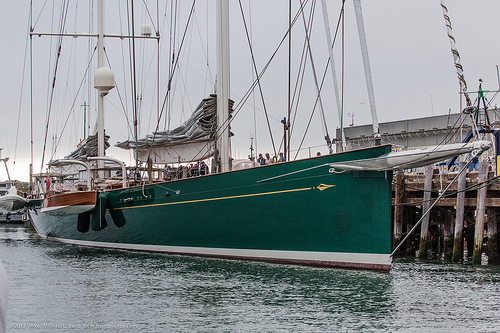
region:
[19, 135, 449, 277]
a green sail boat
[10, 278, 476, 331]
the water is calm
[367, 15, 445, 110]
the sky is gray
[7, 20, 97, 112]
the sky is cloudy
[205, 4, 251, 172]
the pole is tall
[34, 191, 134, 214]
a lifeboat attached to the sail boat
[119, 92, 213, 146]
the sails are down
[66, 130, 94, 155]
the sails are gray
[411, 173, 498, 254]
the dock is wooden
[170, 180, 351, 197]
a gold arrow is painted on the side of the boat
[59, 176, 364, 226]
yellow arrow on side of boat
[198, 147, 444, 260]
yellow arrow on side of boat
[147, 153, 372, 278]
yellow arrow on side of boat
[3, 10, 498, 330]
Exterior shot, harbor setting.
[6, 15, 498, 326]
Daytime, outside view, featuring grey sky and waterway, abutting harbor.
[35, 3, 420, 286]
Docked, green boat.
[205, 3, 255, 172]
White mast of boat.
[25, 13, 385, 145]
Many rigging lines visible.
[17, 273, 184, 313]
Calm, lightly rippling water.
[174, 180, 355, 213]
Thin stripe on green boat.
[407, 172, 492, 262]
Pier structure with partially painted struts.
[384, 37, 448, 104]
Deep, grey sky with no sun visible.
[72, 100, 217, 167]
Folded sails.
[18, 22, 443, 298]
The boat is green and white with a yellow stripe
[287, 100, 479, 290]
The boat is docked to the pier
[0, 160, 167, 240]
The boat has two life boats on the right side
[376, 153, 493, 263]
The pier has many tall wooden columns holding it up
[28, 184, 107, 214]
The smaller boat is brown and white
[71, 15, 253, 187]
The mast is white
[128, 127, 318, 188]
A crowd gathers on the pier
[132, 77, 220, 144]
The white sail is folded on top of itself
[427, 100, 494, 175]
A blue boat on the other side of the pier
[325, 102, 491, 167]
A large grey building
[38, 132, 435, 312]
boat is large and green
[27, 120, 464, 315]
boat is large and green